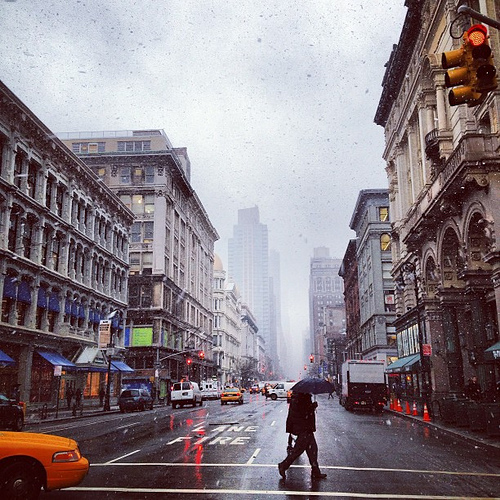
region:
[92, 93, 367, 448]
snowing on a city street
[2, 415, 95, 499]
yellow city taxi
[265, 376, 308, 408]
white van driving across street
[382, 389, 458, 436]
reflective orange safety cones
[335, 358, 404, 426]
white box truck parked on city street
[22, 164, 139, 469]
tall city building with multi levels of windows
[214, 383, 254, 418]
yellow taxi driving down city street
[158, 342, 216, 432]
red stoplights hanging from metal pole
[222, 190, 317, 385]
large skyscraper at a distance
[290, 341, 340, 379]
red stoplights hanging over city street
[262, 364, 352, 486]
person crossing street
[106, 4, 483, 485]
a city landscape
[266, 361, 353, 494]
a person carrying an umbrella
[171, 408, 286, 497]
fire lane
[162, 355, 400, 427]
cars on a city street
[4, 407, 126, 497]
a taxi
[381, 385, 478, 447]
orange cones beside the road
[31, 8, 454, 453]
a rainy day in the city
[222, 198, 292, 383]
a skyscraper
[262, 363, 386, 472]
the person is wearing black and carrying an umbrella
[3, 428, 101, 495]
the cab is yellow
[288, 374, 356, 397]
the umbrella is blue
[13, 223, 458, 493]
it is raining in the photo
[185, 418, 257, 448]
fire lane is white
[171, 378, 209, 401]
the van is white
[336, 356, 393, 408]
the lorry is white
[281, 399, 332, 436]
the top is black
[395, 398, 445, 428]
the cones are yellow and white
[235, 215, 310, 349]
the building is the tallest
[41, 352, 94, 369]
the building is blue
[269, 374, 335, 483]
Man walking in middle of crosswalk.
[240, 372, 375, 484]
Man walking across street holding an umbrella.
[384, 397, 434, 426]
Orange and white traffic cones on the curb.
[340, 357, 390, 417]
White truck parked beside the curb.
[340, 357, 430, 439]
Truck on the street beside the curb.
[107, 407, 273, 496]
Street lane for fire trucks.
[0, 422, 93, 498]
Orange cab preparing to turn left onto street.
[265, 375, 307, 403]
White truck moving on a busy street.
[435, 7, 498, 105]
Yellow traffic light on a black pole.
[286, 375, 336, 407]
Blue umbrella in man's hand walking across the street.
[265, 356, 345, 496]
A person walking with their umbrella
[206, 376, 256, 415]
A yellow taxi driving down the street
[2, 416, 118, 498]
A yellow taxi turning onto the street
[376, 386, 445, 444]
Orange cones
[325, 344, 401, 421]
A white truck parked on the side of the road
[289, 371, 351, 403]
A black umbrella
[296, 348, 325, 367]
A red traffic light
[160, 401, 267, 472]
A Fire Lane sign in the street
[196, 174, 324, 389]
A tall building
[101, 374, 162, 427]
A van parked on the side of the road